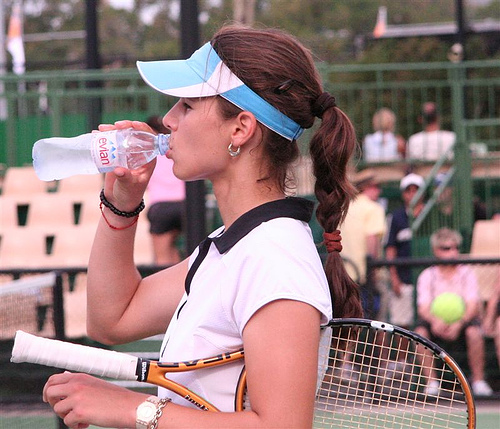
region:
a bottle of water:
[15, 111, 184, 186]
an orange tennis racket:
[4, 319, 494, 426]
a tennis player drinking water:
[12, 19, 357, 427]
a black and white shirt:
[148, 204, 330, 427]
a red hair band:
[307, 197, 367, 257]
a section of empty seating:
[5, 157, 164, 334]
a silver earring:
[222, 136, 249, 167]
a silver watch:
[118, 390, 177, 427]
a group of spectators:
[325, 96, 499, 371]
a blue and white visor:
[138, 40, 318, 150]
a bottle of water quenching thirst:
[30, 116, 189, 177]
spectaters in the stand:
[364, 114, 499, 311]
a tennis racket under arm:
[16, 305, 455, 427]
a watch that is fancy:
[116, 390, 156, 424]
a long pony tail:
[274, 46, 394, 350]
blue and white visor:
[121, 51, 321, 158]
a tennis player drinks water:
[18, 23, 431, 323]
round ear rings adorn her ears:
[221, 123, 250, 168]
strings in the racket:
[330, 327, 442, 417]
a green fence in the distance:
[13, 59, 143, 137]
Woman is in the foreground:
[21, 10, 401, 427]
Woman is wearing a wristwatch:
[114, 385, 176, 427]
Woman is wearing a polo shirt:
[144, 186, 354, 426]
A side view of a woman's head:
[110, 3, 372, 208]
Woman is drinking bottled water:
[21, 16, 360, 246]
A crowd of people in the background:
[293, 97, 499, 399]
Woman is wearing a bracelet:
[91, 178, 150, 239]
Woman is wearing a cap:
[125, 15, 361, 226]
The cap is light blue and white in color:
[120, 8, 350, 213]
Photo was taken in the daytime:
[2, 2, 498, 427]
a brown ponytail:
[302, 92, 369, 322]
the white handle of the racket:
[14, 326, 148, 382]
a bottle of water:
[28, 133, 171, 177]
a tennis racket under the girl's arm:
[16, 321, 478, 426]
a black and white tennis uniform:
[154, 199, 319, 427]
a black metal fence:
[0, 262, 496, 399]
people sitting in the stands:
[337, 111, 497, 397]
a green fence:
[3, 73, 495, 169]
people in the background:
[337, 108, 492, 339]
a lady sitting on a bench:
[400, 230, 476, 361]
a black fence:
[350, 262, 490, 347]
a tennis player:
[5, 75, 390, 400]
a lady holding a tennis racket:
[30, 48, 467, 418]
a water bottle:
[25, 122, 158, 167]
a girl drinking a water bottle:
[23, 72, 369, 423]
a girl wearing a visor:
[21, 81, 413, 414]